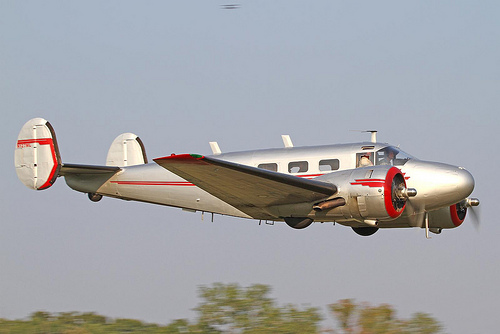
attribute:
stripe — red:
[110, 175, 197, 189]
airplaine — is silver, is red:
[16, 120, 488, 230]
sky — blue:
[80, 52, 315, 107]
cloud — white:
[7, 255, 49, 297]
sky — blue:
[261, 39, 425, 90]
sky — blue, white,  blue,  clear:
[4, 2, 497, 116]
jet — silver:
[14, 104, 482, 243]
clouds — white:
[168, 14, 354, 81]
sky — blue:
[75, 222, 264, 275]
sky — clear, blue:
[1, 1, 495, 332]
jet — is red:
[21, 112, 486, 239]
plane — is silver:
[7, 92, 491, 248]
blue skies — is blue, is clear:
[0, 0, 500, 332]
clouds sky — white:
[264, 22, 441, 98]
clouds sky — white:
[12, 7, 237, 104]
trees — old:
[186, 278, 443, 331]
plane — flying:
[13, 115, 482, 239]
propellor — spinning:
[458, 191, 483, 229]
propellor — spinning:
[393, 161, 427, 231]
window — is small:
[353, 149, 373, 169]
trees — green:
[189, 271, 442, 331]